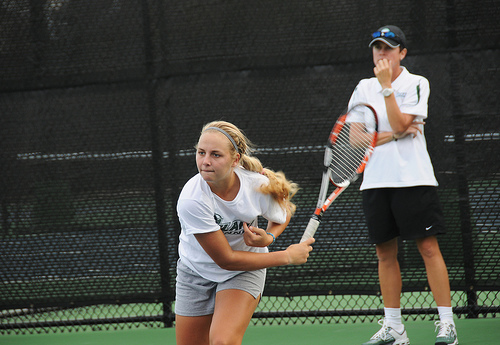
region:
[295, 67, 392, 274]
Girl holding a tennis racket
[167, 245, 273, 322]
woman wearing gray shorts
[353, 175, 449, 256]
man wearing black shorts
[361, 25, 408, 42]
man wearing sunglasses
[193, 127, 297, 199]
girl with blonde hair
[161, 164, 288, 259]
woman wearing a white shirt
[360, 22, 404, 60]
woman wearing a black hat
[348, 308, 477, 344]
woman wearing gray and white shoes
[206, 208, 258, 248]
logo on a tee shirt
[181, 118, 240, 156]
woman wearing a headband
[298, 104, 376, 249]
red and black tennis racquet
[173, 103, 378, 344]
girl swinging a tennis racquet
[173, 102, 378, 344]
girl paying tennis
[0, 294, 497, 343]
green tennis court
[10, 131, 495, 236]
tennis net behind black tarp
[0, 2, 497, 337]
black chain link fence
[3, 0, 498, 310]
black net around tenis court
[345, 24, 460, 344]
man watching tennis player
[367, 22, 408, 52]
glasses on a black cap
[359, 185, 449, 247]
black Nike shorts with white logo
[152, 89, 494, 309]
a woman on a tennis court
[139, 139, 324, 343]
a woman playing tennis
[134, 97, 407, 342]
a woman holding a racket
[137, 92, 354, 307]
a woman holding a tennis racket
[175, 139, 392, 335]
a woman swinging a racket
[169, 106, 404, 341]
a woman swinging a tenni racket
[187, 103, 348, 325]
a woman with blonde hair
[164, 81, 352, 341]
a woman with long hair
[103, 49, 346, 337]
a woman with hair up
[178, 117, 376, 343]
a lady holding a tennis racket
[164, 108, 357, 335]
a lady playing tennis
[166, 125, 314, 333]
a lady in a white shirt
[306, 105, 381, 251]
a tennis racket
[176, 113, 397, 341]
a lady swinging a tennis racket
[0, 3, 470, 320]
a black fence behind the tennis court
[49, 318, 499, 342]
the green ground on the tennis court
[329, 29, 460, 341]
a man in a white shirt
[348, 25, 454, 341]
a man in a black hat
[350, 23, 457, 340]
a man watching the tennis game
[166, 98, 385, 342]
blonde girl playing tennis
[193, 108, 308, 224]
girl's long blonde hair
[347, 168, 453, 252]
baggy black nike shorts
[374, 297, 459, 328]
ankle high white socks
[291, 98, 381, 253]
red black and white tennis racket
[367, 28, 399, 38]
reflective blue sun glasses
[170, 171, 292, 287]
baggy white tee shirt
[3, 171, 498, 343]
green and blue tennis court floors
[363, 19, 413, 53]
white, black, and grey base ball cap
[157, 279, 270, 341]
girl's tan lower thighs